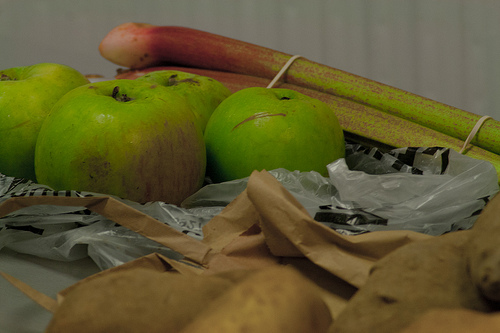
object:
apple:
[202, 88, 349, 177]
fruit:
[97, 23, 499, 149]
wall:
[1, 0, 500, 123]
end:
[91, 22, 157, 71]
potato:
[39, 256, 223, 332]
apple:
[32, 81, 208, 207]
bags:
[1, 146, 499, 258]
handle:
[1, 191, 207, 307]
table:
[1, 139, 497, 331]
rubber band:
[264, 54, 300, 89]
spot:
[88, 162, 106, 177]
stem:
[110, 83, 123, 102]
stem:
[281, 95, 291, 101]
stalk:
[244, 47, 500, 149]